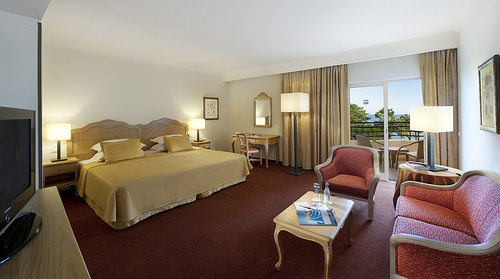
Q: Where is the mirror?
A: Above the desk.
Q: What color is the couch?
A: Red.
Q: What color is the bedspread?
A: Yellow.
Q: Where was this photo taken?
A: A hotel room.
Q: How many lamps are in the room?
A: Four.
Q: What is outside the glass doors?
A: A balcony.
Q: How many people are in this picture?
A: Zero.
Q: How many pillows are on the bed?
A: Six.